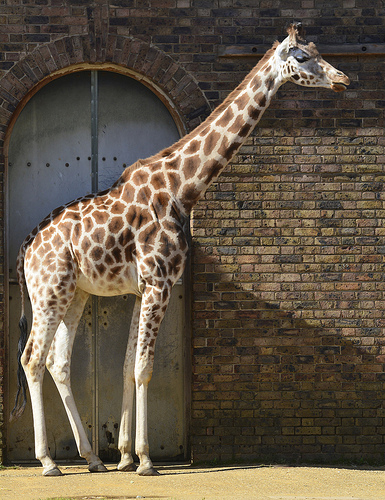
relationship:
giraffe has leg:
[9, 22, 350, 476] [17, 256, 75, 473]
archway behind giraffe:
[0, 32, 196, 469] [15, 17, 336, 497]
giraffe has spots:
[9, 22, 350, 476] [14, 54, 335, 382]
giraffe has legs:
[9, 22, 350, 476] [19, 363, 174, 480]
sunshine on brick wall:
[0, 32, 381, 498] [193, 97, 384, 462]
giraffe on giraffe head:
[9, 22, 350, 476] [275, 22, 349, 91]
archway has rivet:
[0, 32, 196, 469] [108, 150, 120, 166]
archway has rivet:
[0, 32, 196, 469] [60, 160, 73, 171]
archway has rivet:
[0, 32, 196, 469] [22, 157, 36, 171]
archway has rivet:
[0, 32, 196, 469] [174, 292, 185, 305]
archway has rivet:
[0, 32, 196, 469] [100, 307, 111, 319]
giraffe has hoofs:
[9, 22, 350, 476] [34, 458, 165, 481]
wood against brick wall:
[215, 41, 384, 58] [1, 0, 384, 472]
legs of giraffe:
[20, 328, 92, 459] [19, 29, 352, 430]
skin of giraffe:
[93, 199, 155, 251] [9, 22, 350, 476]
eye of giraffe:
[291, 51, 314, 68] [9, 22, 350, 476]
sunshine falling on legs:
[6, 24, 382, 499] [18, 243, 171, 478]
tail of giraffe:
[8, 256, 26, 422] [9, 22, 350, 476]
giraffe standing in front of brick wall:
[9, 22, 350, 476] [1, 0, 384, 472]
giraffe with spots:
[9, 22, 350, 476] [15, 23, 348, 382]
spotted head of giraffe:
[252, 16, 359, 99] [9, 22, 350, 476]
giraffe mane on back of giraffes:
[118, 42, 277, 171] [15, 21, 351, 327]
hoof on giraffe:
[83, 462, 108, 471] [9, 22, 350, 476]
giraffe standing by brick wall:
[9, 22, 350, 476] [1, 0, 384, 472]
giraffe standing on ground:
[9, 22, 350, 476] [0, 460, 382, 497]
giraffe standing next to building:
[9, 22, 350, 476] [1, 2, 381, 465]